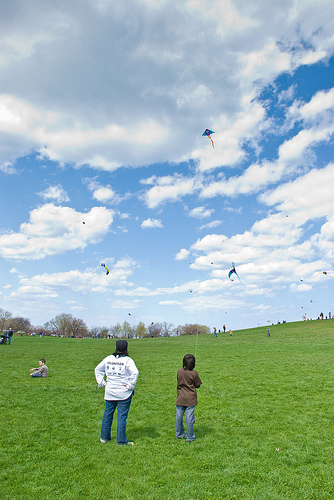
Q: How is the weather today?
A: It is cloudy.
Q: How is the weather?
A: It is cloudy.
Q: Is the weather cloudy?
A: Yes, it is cloudy.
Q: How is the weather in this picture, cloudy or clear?
A: It is cloudy.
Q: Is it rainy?
A: No, it is cloudy.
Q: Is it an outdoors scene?
A: Yes, it is outdoors.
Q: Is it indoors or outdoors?
A: It is outdoors.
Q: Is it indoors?
A: No, it is outdoors.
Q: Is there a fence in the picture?
A: No, there are no fences.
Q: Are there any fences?
A: No, there are no fences.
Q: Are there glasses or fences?
A: No, there are no fences or glasses.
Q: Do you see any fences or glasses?
A: No, there are no fences or glasses.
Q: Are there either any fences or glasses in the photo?
A: No, there are no fences or glasses.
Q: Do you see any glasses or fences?
A: No, there are no fences or glasses.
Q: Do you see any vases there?
A: No, there are no vases.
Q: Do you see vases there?
A: No, there are no vases.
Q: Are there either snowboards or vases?
A: No, there are no vases or snowboards.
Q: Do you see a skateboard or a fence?
A: No, there are no fences or skateboards.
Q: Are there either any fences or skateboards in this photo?
A: No, there are no fences or skateboards.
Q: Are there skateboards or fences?
A: No, there are no fences or skateboards.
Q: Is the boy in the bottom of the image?
A: Yes, the boy is in the bottom of the image.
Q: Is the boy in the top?
A: No, the boy is in the bottom of the image.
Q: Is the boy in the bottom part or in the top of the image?
A: The boy is in the bottom of the image.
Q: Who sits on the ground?
A: The boy sits on the ground.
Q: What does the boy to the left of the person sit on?
A: The boy sits on the ground.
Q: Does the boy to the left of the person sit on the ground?
A: Yes, the boy sits on the ground.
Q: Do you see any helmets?
A: No, there are no helmets.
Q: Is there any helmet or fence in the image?
A: No, there are no helmets or fences.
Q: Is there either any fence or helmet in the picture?
A: No, there are no helmets or fences.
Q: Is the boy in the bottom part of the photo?
A: Yes, the boy is in the bottom of the image.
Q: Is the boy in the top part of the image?
A: No, the boy is in the bottom of the image.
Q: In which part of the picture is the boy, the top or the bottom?
A: The boy is in the bottom of the image.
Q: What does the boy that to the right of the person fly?
A: The boy flies the kite.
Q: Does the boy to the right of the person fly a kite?
A: Yes, the boy flies a kite.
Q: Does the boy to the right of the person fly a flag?
A: No, the boy flies a kite.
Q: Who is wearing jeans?
A: The boy is wearing jeans.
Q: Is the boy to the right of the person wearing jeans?
A: Yes, the boy is wearing jeans.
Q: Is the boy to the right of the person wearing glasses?
A: No, the boy is wearing jeans.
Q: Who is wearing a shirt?
A: The boy is wearing a shirt.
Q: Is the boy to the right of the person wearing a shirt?
A: Yes, the boy is wearing a shirt.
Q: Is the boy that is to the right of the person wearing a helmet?
A: No, the boy is wearing a shirt.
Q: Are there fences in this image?
A: No, there are no fences.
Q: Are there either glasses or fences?
A: No, there are no fences or glasses.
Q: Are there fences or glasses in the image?
A: No, there are no fences or glasses.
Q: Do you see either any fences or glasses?
A: No, there are no fences or glasses.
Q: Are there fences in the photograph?
A: No, there are no fences.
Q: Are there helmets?
A: No, there are no helmets.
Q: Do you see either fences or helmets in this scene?
A: No, there are no helmets or fences.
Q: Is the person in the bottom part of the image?
A: Yes, the person is in the bottom of the image.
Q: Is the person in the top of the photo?
A: No, the person is in the bottom of the image.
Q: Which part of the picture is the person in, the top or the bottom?
A: The person is in the bottom of the image.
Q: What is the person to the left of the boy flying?
A: The person is flying the kite.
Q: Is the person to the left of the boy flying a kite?
A: Yes, the person is flying a kite.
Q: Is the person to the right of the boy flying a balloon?
A: No, the person is flying a kite.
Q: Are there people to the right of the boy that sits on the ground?
A: Yes, there is a person to the right of the boy.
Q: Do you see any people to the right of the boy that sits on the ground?
A: Yes, there is a person to the right of the boy.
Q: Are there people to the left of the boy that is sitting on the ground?
A: No, the person is to the right of the boy.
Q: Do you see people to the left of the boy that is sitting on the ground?
A: No, the person is to the right of the boy.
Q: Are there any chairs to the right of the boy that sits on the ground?
A: No, there is a person to the right of the boy.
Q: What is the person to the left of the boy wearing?
A: The person is wearing jeans.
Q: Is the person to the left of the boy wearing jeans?
A: Yes, the person is wearing jeans.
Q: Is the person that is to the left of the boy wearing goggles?
A: No, the person is wearing jeans.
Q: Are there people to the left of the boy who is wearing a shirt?
A: Yes, there is a person to the left of the boy.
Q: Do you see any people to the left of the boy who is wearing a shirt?
A: Yes, there is a person to the left of the boy.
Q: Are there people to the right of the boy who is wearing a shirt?
A: No, the person is to the left of the boy.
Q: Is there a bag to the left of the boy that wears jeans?
A: No, there is a person to the left of the boy.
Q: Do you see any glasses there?
A: No, there are no glasses.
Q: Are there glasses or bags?
A: No, there are no glasses or bags.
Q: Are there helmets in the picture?
A: No, there are no helmets.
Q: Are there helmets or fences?
A: No, there are no helmets or fences.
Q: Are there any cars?
A: No, there are no cars.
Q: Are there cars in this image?
A: No, there are no cars.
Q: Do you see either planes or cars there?
A: No, there are no cars or planes.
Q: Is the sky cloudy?
A: Yes, the sky is cloudy.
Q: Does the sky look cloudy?
A: Yes, the sky is cloudy.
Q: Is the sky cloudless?
A: No, the sky is cloudy.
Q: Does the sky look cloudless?
A: No, the sky is cloudy.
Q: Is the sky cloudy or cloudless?
A: The sky is cloudy.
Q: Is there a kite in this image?
A: Yes, there is a kite.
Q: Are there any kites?
A: Yes, there is a kite.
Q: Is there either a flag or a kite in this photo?
A: Yes, there is a kite.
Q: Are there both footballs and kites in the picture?
A: No, there is a kite but no footballs.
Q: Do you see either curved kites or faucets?
A: Yes, there is a curved kite.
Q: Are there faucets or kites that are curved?
A: Yes, the kite is curved.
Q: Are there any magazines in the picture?
A: No, there are no magazines.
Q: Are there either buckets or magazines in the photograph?
A: No, there are no magazines or buckets.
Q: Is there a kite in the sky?
A: Yes, there is a kite in the sky.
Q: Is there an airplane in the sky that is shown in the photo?
A: No, there is a kite in the sky.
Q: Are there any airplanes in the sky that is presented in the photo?
A: No, there is a kite in the sky.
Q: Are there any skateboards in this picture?
A: No, there are no skateboards.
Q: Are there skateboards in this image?
A: No, there are no skateboards.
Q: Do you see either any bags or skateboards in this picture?
A: No, there are no skateboards or bags.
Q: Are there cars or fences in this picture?
A: No, there are no fences or cars.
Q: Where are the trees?
A: The trees are on the hill.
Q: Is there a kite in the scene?
A: Yes, there is a kite.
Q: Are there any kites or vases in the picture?
A: Yes, there is a kite.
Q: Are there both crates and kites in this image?
A: No, there is a kite but no crates.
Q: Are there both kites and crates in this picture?
A: No, there is a kite but no crates.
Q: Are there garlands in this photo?
A: No, there are no garlands.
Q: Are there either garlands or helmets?
A: No, there are no garlands or helmets.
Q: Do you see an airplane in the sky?
A: No, there is a kite in the sky.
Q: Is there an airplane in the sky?
A: No, there is a kite in the sky.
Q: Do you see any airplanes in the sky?
A: No, there is a kite in the sky.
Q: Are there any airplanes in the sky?
A: No, there is a kite in the sky.